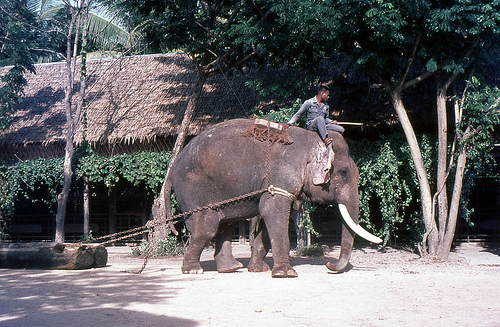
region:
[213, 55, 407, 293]
man riding the elephant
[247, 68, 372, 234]
man riding the elephant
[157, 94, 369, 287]
the elephant is brown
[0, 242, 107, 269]
two logs dragged on ground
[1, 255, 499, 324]
dirt road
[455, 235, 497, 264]
dirt path between trees beside a road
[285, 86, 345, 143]
man sitting on an elephant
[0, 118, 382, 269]
elephant pulling logs on a dirt path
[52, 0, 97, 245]
trees standing beside a dirt road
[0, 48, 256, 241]
structure with a straw roof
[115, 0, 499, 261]
trees standing beside a dirt road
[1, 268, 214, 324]
shadow cast on dirt road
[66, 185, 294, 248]
chain and rope connecting elephant and logs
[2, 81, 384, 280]
an elephant is pulling some logs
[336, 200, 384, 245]
white tusks on an elephant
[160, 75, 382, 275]
a man is riding an elephant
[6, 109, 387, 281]
logs are chained to an elephant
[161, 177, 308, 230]
chain is fixed to an elephants leg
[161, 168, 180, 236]
tail of an elephant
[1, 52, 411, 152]
thatched roof of a building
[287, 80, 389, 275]
man sits on an elephants head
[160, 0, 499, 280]
tree behind an elephant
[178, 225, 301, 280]
four elephant feet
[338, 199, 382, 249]
the big tusks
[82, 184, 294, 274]
a chain on leg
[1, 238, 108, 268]
logs on ground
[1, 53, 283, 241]
a hut house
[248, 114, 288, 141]
saddle on back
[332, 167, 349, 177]
eyes are open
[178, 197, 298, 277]
legs of animal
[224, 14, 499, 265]
tree to right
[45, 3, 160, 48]
palm tree behind hut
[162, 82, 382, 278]
a elephant walking in park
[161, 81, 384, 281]
a man on an elephant.